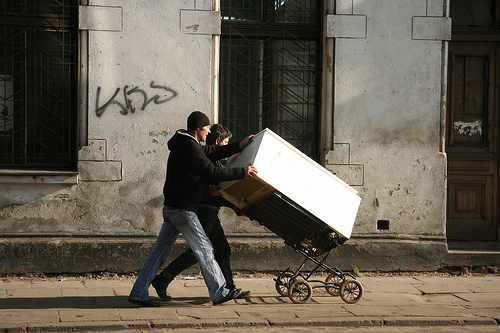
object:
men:
[126, 109, 258, 307]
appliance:
[214, 126, 367, 255]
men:
[154, 124, 252, 300]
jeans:
[128, 206, 228, 304]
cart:
[272, 233, 365, 308]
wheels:
[339, 280, 364, 304]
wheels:
[324, 274, 347, 296]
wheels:
[287, 279, 313, 303]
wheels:
[276, 271, 300, 296]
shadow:
[1, 292, 160, 314]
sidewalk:
[2, 268, 500, 324]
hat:
[187, 110, 211, 133]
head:
[186, 111, 211, 143]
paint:
[93, 80, 179, 118]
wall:
[0, 0, 452, 273]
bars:
[220, 0, 324, 167]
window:
[214, 1, 329, 157]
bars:
[3, 2, 85, 174]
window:
[1, 2, 82, 171]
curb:
[4, 321, 500, 332]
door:
[446, 34, 500, 245]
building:
[1, 1, 500, 279]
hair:
[207, 123, 231, 146]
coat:
[162, 128, 245, 213]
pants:
[172, 206, 234, 293]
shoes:
[212, 289, 243, 306]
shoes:
[128, 297, 161, 307]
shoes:
[236, 291, 252, 298]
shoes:
[150, 272, 173, 301]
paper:
[453, 121, 484, 136]